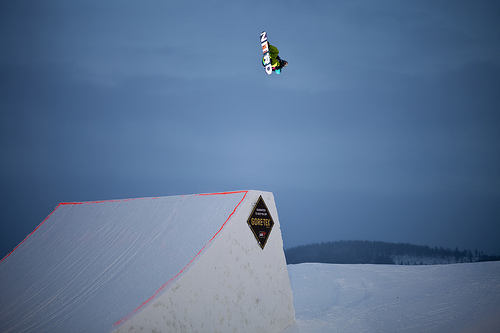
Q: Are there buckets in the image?
A: No, there are no buckets.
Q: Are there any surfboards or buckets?
A: No, there are no buckets or surfboards.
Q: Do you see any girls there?
A: No, there are no girls.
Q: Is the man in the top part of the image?
A: Yes, the man is in the top of the image.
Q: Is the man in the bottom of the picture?
A: No, the man is in the top of the image.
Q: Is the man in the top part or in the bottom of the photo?
A: The man is in the top of the image.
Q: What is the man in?
A: The man is in the air.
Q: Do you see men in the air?
A: Yes, there is a man in the air.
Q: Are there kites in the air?
A: No, there is a man in the air.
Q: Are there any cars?
A: No, there are no cars.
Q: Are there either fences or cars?
A: No, there are no cars or fences.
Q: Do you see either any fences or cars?
A: No, there are no cars or fences.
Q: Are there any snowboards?
A: Yes, there is a snowboard.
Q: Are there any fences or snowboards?
A: Yes, there is a snowboard.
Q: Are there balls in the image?
A: No, there are no balls.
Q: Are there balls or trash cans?
A: No, there are no balls or trash cans.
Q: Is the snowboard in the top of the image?
A: Yes, the snowboard is in the top of the image.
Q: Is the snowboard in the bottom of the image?
A: No, the snowboard is in the top of the image.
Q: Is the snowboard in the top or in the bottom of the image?
A: The snowboard is in the top of the image.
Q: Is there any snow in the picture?
A: Yes, there is snow.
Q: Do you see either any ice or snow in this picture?
A: Yes, there is snow.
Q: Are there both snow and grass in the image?
A: No, there is snow but no grass.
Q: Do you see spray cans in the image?
A: No, there are no spray cans.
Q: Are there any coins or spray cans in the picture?
A: No, there are no spray cans or coins.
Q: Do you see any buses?
A: No, there are no buses.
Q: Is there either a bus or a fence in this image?
A: No, there are no buses or fences.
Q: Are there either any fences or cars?
A: No, there are no cars or fences.